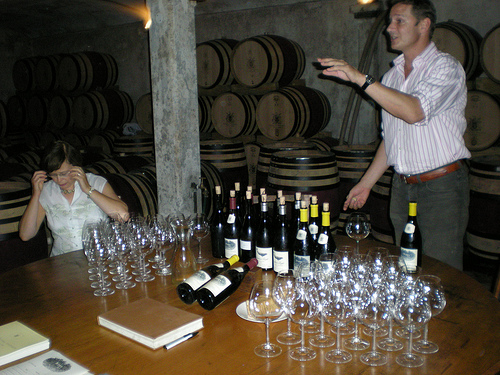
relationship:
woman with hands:
[17, 139, 128, 256] [29, 164, 90, 189]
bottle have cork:
[175, 183, 423, 309] [215, 182, 335, 212]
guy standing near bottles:
[311, 0, 475, 272] [216, 180, 423, 291]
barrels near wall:
[16, 24, 496, 243] [18, 4, 496, 151]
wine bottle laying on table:
[177, 255, 260, 310] [20, 220, 477, 369]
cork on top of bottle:
[205, 176, 335, 226] [201, 179, 338, 283]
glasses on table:
[241, 250, 459, 369] [20, 220, 477, 369]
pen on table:
[161, 326, 203, 353] [0, 219, 500, 374]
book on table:
[98, 296, 204, 349] [0, 219, 500, 374]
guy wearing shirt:
[303, 6, 492, 278] [349, 32, 494, 187]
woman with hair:
[17, 139, 128, 256] [31, 139, 91, 178]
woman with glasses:
[17, 139, 128, 256] [39, 169, 70, 178]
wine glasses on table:
[246, 249, 446, 366] [0, 219, 500, 374]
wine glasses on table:
[81, 204, 210, 304] [0, 219, 500, 374]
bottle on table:
[175, 183, 423, 309] [0, 219, 500, 374]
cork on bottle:
[215, 182, 335, 212] [223, 190, 238, 262]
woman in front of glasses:
[14, 144, 129, 254] [78, 208, 213, 295]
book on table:
[98, 296, 204, 352] [62, 190, 448, 365]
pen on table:
[163, 330, 200, 350] [62, 190, 448, 365]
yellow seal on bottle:
[406, 200, 424, 221] [222, 185, 339, 284]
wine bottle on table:
[198, 255, 260, 309] [0, 219, 500, 374]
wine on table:
[202, 170, 338, 280] [4, 198, 492, 373]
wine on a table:
[175, 180, 424, 311] [20, 220, 477, 369]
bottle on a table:
[294, 188, 346, 273] [20, 220, 477, 369]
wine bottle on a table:
[207, 182, 336, 279] [0, 219, 500, 374]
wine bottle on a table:
[399, 198, 421, 273] [0, 219, 500, 374]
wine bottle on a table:
[239, 190, 258, 270] [0, 219, 500, 374]